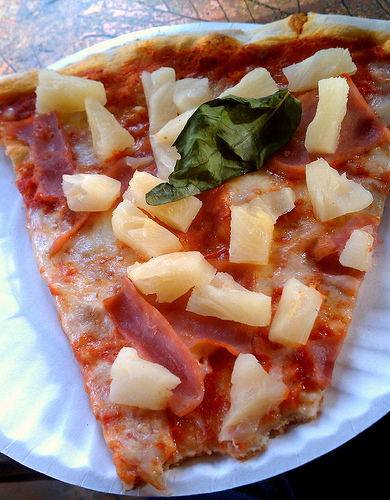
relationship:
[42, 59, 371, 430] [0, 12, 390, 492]
pineapple on top of melted cheese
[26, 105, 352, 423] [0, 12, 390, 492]
bacon on top of melted cheese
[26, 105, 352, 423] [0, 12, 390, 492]
bacon on melted cheese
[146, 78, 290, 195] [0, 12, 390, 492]
leaf on melted cheese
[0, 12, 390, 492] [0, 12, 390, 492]
melted cheese on melted cheese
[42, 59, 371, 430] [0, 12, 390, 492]
pineapple on melted cheese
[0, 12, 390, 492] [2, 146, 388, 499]
melted cheese on paper plate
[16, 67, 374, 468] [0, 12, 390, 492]
melted cheese on melted cheese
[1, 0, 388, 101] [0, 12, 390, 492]
crust of melted cheese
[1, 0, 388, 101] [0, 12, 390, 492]
crust on melted cheese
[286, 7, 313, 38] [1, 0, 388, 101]
spot on crust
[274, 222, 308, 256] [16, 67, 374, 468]
oily spot on melted cheese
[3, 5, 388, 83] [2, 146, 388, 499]
countertop under paper plate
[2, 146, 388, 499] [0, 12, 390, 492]
paper plate underneath melted cheese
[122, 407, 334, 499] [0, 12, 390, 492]
bite mark in melted cheese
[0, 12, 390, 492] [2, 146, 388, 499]
melted cheese on a paper plate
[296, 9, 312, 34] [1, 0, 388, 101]
crack in crust